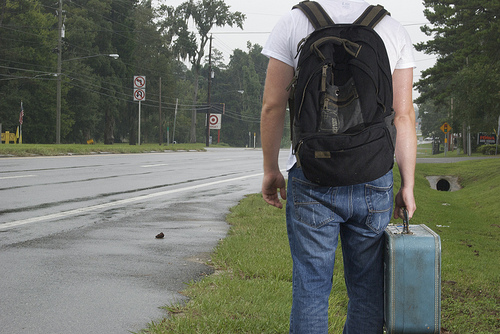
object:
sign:
[201, 107, 226, 126]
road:
[0, 131, 297, 334]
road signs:
[129, 73, 154, 103]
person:
[260, 0, 419, 333]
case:
[382, 204, 442, 334]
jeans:
[287, 159, 396, 334]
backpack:
[278, 2, 404, 192]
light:
[35, 6, 229, 151]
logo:
[206, 114, 219, 125]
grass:
[158, 140, 499, 334]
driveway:
[371, 140, 498, 175]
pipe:
[421, 172, 465, 191]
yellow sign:
[437, 118, 459, 143]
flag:
[10, 93, 33, 147]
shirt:
[259, 2, 422, 76]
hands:
[252, 171, 414, 221]